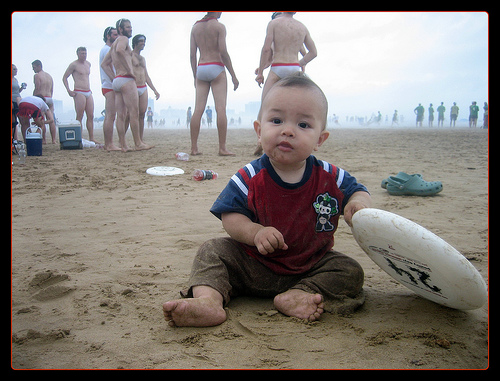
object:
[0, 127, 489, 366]
beach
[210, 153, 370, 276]
shirt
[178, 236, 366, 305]
pants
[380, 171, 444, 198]
shoes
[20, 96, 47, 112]
shirt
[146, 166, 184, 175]
disc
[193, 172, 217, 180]
drink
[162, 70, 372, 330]
baby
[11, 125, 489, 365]
sand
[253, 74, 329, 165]
head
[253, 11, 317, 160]
person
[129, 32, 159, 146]
person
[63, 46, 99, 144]
person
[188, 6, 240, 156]
man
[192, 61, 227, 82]
swimsuit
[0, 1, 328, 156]
people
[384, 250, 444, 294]
logo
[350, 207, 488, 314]
frisbee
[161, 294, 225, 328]
foot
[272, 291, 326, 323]
foot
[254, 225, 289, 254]
hand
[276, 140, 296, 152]
mouth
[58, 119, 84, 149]
cooler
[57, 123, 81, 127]
lid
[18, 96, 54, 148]
person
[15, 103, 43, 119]
shorts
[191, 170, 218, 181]
bottle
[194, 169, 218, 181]
liquid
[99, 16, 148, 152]
guy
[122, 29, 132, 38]
beard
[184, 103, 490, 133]
people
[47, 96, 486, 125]
ocean